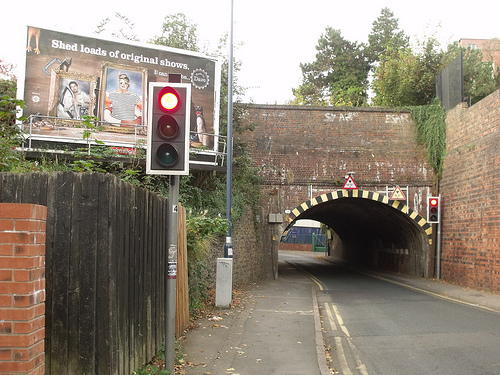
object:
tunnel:
[273, 196, 429, 281]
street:
[0, 240, 500, 375]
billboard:
[14, 25, 226, 172]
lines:
[271, 188, 432, 246]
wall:
[239, 92, 500, 299]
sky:
[251, 0, 300, 71]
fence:
[436, 57, 462, 112]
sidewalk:
[180, 261, 324, 375]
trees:
[291, 24, 370, 105]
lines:
[323, 302, 368, 375]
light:
[161, 92, 179, 110]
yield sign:
[342, 175, 358, 189]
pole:
[165, 176, 179, 373]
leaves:
[395, 77, 425, 105]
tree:
[369, 21, 495, 108]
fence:
[0, 174, 187, 374]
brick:
[440, 88, 499, 294]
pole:
[224, 0, 233, 258]